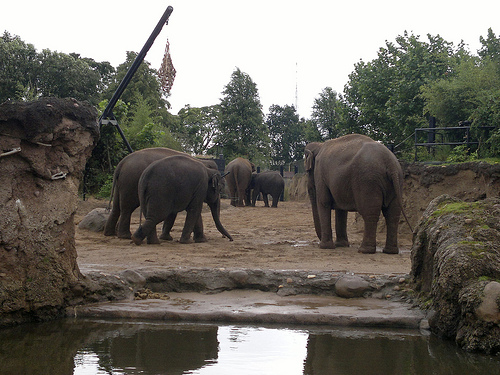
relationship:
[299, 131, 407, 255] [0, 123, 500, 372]
elephant in pen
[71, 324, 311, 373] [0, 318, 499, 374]
reflection on water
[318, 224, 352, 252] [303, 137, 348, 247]
feet on front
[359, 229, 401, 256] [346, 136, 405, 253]
feet on back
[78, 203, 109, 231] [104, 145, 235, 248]
stone by elephants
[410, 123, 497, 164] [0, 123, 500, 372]
fence of pen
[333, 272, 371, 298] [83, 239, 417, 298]
rock in mud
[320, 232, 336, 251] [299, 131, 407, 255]
foot on elephant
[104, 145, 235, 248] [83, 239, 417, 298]
elephants in mud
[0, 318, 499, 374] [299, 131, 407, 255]
water by elephant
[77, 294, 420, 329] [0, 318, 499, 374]
step by water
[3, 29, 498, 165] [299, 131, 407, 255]
trees by elephant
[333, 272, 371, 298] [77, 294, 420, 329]
rock on step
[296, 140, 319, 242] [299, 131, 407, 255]
head of elephant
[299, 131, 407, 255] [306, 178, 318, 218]
elephant has a tusk